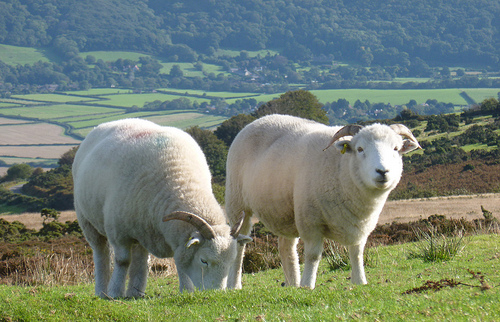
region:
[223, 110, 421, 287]
White sheep with horns to the right of another.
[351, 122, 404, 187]
Head of a white sheep looking at the camera.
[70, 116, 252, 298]
White sheep with it's head down.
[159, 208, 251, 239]
Tan horns on a sheep with it's head down.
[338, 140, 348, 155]
Yellow tag in the ear of a white sheep.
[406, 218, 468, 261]
Tall grass to the right of a right side sheep.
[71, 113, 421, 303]
Two white sheep on a hillside.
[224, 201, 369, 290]
All the white legs on the right side sheep.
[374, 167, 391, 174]
Black nose on the right side sheep.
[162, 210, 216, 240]
Brown horn on the left side of the left sheeps head.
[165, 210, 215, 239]
The left horn on the sheep's head on the left.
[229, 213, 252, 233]
The right horn on the sheep's head on the left.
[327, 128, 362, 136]
The left horn on the sheep's head on the right.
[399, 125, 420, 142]
The right horn on the sheep's head on the right .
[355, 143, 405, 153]
The eyes of the sheep on the right.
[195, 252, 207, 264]
The eye of the sheep on the left.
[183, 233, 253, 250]
The ears of the sheep on the left.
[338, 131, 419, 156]
The ears of the sheep on the right.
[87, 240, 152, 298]
The legs of the sheep on the left.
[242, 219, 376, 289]
The legs of the sheep on the right.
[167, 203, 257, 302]
The head of the sheep on the left.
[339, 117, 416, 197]
The head of the sheep on the right.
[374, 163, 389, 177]
The nose of the sheep on the right.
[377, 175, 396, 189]
The mouth of the sheep on the right.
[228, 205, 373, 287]
The legs of the sheep on the right.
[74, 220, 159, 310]
The legs of the sheep on the left.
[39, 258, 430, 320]
The grass area where the sheep are standing.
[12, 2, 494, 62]
The trees in the distance.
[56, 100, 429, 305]
Two sheeps on the mountain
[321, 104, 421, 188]
Goat with two horns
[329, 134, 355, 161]
Goat with tags on the ear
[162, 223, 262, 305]
goat with there head down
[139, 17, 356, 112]
Wilderness in the distance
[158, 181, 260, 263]
Horns on top of the goat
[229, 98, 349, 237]
Goat with white wool coat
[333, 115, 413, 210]
goat looking straight ahead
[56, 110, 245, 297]
Goat eating grass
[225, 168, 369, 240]
Goat with white sheep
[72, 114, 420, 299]
two sheep on the grass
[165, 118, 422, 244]
the animals have horns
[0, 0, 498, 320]
the field is green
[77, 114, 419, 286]
the animals are white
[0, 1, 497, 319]
the field is full of trees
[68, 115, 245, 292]
the animal is eating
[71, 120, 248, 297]
the animal is grazing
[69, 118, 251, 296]
the animal is looking down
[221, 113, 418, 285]
the animal is looking forward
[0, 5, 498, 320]
the scene takes place outdoors